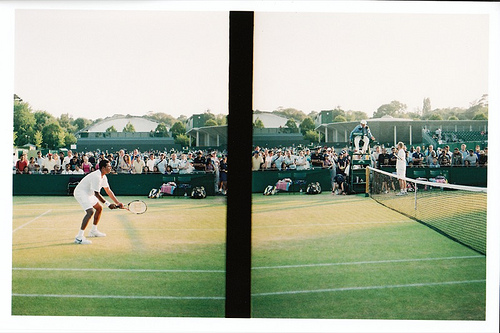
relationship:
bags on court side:
[268, 174, 338, 210] [15, 156, 385, 215]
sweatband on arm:
[101, 190, 125, 213] [86, 174, 124, 229]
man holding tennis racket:
[72, 159, 124, 245] [109, 200, 147, 215]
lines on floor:
[20, 271, 204, 322] [27, 237, 497, 316]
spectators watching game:
[19, 146, 438, 174] [13, 159, 429, 297]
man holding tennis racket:
[72, 159, 124, 245] [106, 195, 151, 215]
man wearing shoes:
[68, 156, 141, 243] [75, 221, 104, 243]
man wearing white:
[72, 159, 124, 245] [69, 170, 110, 212]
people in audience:
[109, 148, 199, 172] [19, 138, 480, 191]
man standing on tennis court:
[72, 159, 124, 245] [23, 191, 475, 309]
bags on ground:
[145, 180, 196, 198] [22, 190, 471, 311]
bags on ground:
[265, 174, 320, 196] [27, 188, 466, 302]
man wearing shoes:
[72, 159, 124, 245] [75, 228, 105, 246]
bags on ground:
[144, 180, 207, 202] [22, 190, 471, 311]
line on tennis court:
[13, 256, 477, 274] [24, 192, 483, 322]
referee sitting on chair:
[352, 121, 373, 151] [345, 137, 369, 191]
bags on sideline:
[153, 179, 203, 196] [19, 168, 484, 194]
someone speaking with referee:
[395, 144, 407, 191] [353, 110, 377, 150]